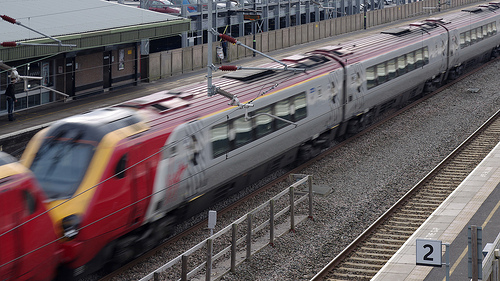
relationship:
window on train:
[228, 109, 254, 154] [2, 1, 498, 280]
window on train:
[245, 103, 282, 146] [2, 1, 498, 280]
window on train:
[28, 124, 104, 198] [2, 1, 498, 280]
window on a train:
[284, 93, 326, 135] [44, 62, 379, 262]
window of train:
[28, 139, 95, 197] [2, 1, 498, 280]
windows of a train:
[210, 123, 235, 159] [17, 15, 498, 258]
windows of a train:
[210, 123, 235, 159] [19, 14, 499, 235]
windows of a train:
[364, 65, 380, 87] [19, 14, 499, 235]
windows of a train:
[364, 65, 380, 87] [2, 1, 498, 280]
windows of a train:
[459, 12, 499, 46] [2, 1, 498, 280]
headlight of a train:
[61, 221, 84, 246] [17, 15, 498, 258]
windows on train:
[206, 86, 311, 156] [17, 15, 498, 258]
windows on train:
[364, 32, 429, 97] [2, 1, 498, 280]